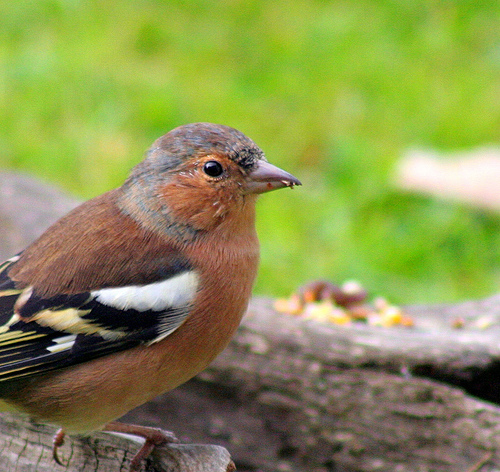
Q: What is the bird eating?
A: Birdseed.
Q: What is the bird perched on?
A: A branch.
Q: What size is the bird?
A: Small.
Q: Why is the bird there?
A: To eat.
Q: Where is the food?
A: On the tree.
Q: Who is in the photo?
A: A bird.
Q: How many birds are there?
A: One.